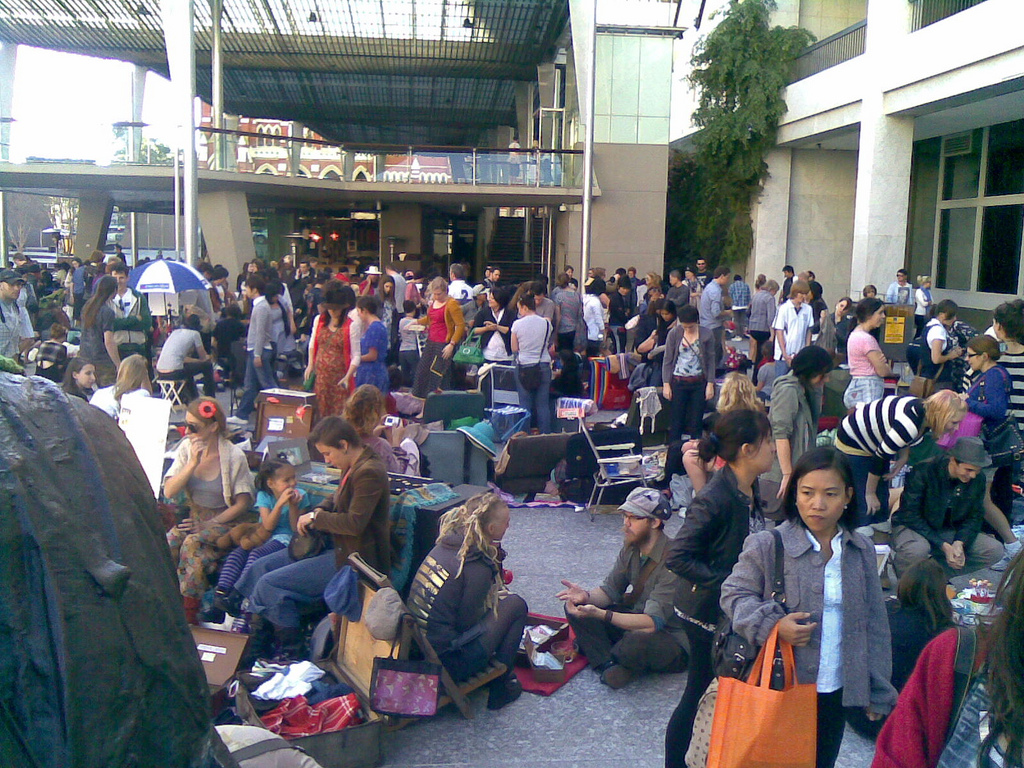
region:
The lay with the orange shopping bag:
[719, 437, 897, 752]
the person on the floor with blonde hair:
[383, 484, 574, 740]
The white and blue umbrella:
[131, 247, 205, 312]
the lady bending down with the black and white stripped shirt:
[836, 382, 967, 499]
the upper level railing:
[190, 105, 596, 205]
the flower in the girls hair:
[193, 402, 228, 421]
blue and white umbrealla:
[119, 255, 218, 300]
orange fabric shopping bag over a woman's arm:
[695, 607, 832, 766]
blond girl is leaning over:
[825, 383, 968, 538]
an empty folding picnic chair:
[568, 411, 671, 520]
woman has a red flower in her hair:
[155, 395, 266, 626]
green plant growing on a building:
[676, 0, 822, 282]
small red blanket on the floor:
[502, 607, 600, 700]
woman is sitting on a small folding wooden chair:
[394, 483, 531, 725]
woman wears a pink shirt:
[838, 294, 900, 412]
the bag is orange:
[708, 622, 817, 766]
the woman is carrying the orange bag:
[684, 443, 903, 764]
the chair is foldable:
[348, 552, 507, 729]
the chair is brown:
[345, 547, 507, 729]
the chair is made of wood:
[342, 549, 511, 730]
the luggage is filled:
[228, 565, 440, 765]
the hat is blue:
[323, 563, 363, 625]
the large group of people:
[2, 243, 1021, 766]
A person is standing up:
[659, 299, 726, 484]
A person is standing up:
[503, 294, 558, 431]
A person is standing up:
[407, 279, 468, 403]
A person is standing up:
[357, 294, 396, 394]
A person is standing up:
[237, 273, 282, 410]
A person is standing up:
[268, 275, 307, 368]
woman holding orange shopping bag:
[710, 617, 828, 766]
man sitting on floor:
[574, 481, 689, 685]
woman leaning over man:
[834, 377, 1003, 580]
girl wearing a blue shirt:
[206, 439, 302, 617]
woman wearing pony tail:
[670, 399, 800, 766]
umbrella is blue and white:
[117, 244, 213, 352]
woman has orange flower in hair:
[166, 398, 258, 634]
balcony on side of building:
[192, 102, 603, 232]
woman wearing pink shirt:
[840, 287, 895, 414]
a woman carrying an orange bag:
[711, 461, 871, 766]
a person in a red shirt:
[420, 285, 460, 383]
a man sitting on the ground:
[580, 497, 701, 678]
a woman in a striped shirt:
[838, 389, 959, 514]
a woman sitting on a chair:
[389, 514, 513, 729]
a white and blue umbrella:
[126, 262, 215, 294]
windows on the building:
[947, 206, 1020, 293]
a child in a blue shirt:
[258, 461, 306, 526]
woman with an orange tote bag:
[703, 446, 896, 761]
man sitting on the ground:
[561, 483, 699, 690]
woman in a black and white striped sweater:
[829, 385, 969, 512]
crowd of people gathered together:
[13, 243, 1022, 763]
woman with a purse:
[506, 293, 560, 429]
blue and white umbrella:
[112, 253, 210, 331]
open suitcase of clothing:
[215, 553, 435, 757]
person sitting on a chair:
[349, 481, 539, 713]